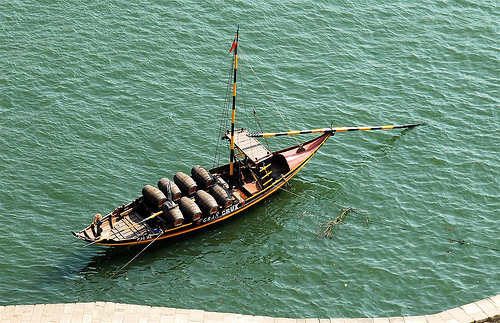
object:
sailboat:
[71, 129, 335, 248]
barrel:
[141, 184, 168, 207]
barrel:
[157, 178, 183, 202]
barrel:
[173, 172, 198, 196]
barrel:
[191, 165, 216, 187]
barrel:
[161, 200, 185, 226]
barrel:
[178, 196, 203, 220]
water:
[0, 0, 500, 316]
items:
[141, 185, 166, 210]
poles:
[249, 122, 429, 138]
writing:
[197, 204, 239, 225]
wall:
[0, 289, 500, 323]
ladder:
[257, 161, 274, 185]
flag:
[230, 39, 238, 54]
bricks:
[460, 302, 490, 321]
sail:
[221, 102, 429, 172]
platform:
[102, 204, 161, 243]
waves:
[440, 45, 467, 56]